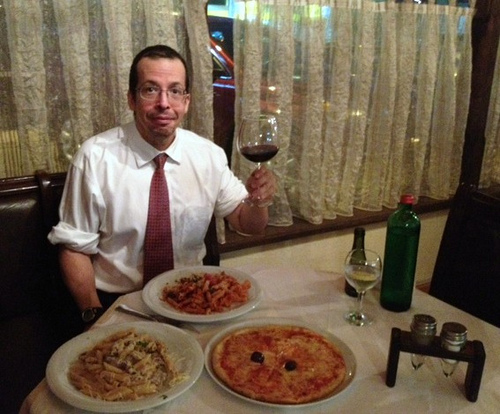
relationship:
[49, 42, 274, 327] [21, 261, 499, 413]
man sitting at table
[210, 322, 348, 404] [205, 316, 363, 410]
pizza on plate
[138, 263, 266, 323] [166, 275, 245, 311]
plate of pasta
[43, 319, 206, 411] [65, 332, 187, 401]
plate of pasta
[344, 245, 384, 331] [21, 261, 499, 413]
wine glass on table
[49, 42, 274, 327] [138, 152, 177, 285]
man wearing tie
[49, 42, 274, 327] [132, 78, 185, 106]
man wearing glasses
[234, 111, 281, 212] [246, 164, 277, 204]
glass in hand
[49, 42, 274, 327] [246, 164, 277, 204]
man has hand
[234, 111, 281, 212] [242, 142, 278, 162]
glass with wine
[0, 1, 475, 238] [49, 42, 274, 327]
curtain behind man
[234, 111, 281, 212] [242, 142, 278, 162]
glass of wine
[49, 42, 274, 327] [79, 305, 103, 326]
man wearing watch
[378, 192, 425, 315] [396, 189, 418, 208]
bottle has cap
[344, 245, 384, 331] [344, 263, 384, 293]
wine glass with wine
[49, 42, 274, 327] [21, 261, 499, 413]
man at table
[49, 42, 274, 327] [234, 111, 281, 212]
man holding glass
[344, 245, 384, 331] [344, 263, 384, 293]
wine glass of wine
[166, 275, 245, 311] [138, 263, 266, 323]
pasta on plate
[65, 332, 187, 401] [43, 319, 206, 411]
pasta on plate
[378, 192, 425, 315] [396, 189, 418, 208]
bottle with cap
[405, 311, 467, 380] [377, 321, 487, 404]
salt & pepper shaker in holder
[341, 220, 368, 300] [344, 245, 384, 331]
bottle behind wine glass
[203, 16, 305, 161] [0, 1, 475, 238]
car behind curtain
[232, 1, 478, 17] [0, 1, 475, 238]
edge of curtain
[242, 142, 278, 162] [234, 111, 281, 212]
wine in glass